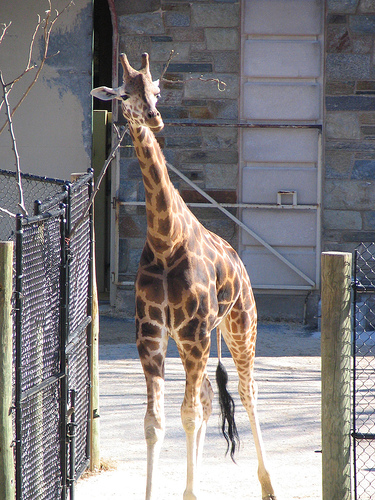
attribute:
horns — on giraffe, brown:
[116, 48, 153, 71]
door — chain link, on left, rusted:
[13, 209, 88, 499]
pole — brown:
[84, 0, 126, 300]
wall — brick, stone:
[109, 1, 373, 218]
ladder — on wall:
[236, 5, 319, 296]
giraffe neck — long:
[125, 131, 183, 232]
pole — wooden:
[321, 252, 354, 499]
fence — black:
[353, 245, 374, 499]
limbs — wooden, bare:
[0, 3, 83, 209]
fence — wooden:
[2, 243, 15, 469]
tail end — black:
[215, 360, 239, 457]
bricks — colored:
[194, 27, 241, 56]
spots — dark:
[152, 164, 169, 212]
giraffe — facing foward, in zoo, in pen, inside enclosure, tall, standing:
[88, 46, 272, 499]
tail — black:
[211, 330, 245, 462]